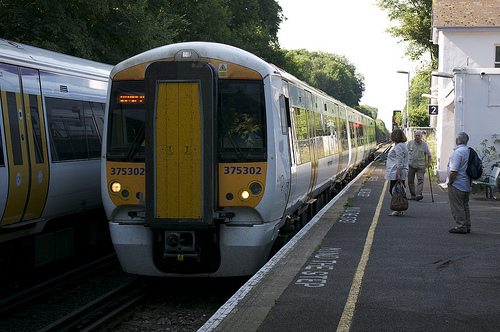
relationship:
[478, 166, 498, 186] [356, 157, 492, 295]
abench at a train station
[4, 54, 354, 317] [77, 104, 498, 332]
two trains at a station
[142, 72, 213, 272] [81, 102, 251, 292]
door on a train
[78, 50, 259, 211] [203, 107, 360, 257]
front of a train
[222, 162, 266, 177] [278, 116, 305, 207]
blue numbers on front of train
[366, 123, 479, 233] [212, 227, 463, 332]
three people standing on platform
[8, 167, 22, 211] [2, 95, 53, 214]
yellow and silver doors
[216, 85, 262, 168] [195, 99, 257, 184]
reflection in front window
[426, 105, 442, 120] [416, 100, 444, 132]
number  sign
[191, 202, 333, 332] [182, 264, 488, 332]
white line on edge of platform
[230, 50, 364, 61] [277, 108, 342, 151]
green leafy trees beside train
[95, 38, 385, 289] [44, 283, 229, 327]
train on tracks